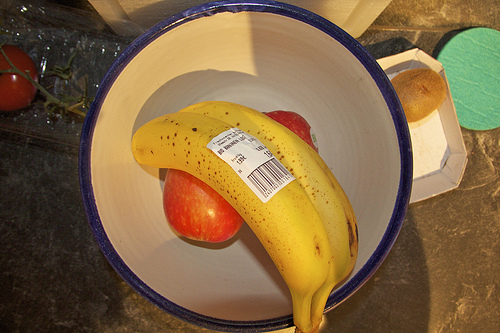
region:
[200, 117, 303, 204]
Sticker on the banana.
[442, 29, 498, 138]
Green disk on counter.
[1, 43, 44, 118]
Tomato on the vine.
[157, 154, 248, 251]
Apple in the bowl.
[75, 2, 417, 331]
Bowl on the counter.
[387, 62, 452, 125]
Kiwi on the container.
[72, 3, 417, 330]
Blue rim on bowl.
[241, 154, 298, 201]
Bar code on the sticker.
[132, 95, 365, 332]
yellow bananas in the bowl.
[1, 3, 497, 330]
Gray marble covering the surface.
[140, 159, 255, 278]
a piece of apple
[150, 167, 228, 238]
a piece of apple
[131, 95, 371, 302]
the bananas have freckles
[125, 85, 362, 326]
the two yellow bananas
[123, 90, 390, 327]
the two yellow bananas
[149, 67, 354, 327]
the two yellow bananas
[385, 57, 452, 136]
a piece of kiwi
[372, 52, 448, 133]
a piece of kiwi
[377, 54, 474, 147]
a piece of kiwi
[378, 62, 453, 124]
a piece of kiwi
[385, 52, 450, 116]
a piece of kiwi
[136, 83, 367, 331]
the bananas in the bowl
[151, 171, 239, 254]
thwe apple under the banana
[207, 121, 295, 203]
the sticker on the banana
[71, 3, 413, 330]
the fruit in the bowl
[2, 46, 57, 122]
the tomatoe on the broken glass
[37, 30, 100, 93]
the borken glass on the ground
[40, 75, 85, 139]
the vine of the tomato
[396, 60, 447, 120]
the brown kiwi in the white carton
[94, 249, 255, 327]
the blue trim of the bowl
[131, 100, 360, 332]
two yellow bananas in the bowl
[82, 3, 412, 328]
blue and white bowl holding fruit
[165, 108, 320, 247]
two red apples under bananas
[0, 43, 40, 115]
red tomato in plastic container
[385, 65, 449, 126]
one small bread roll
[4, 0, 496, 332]
marbled table top under food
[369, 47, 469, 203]
small white beveled edge dish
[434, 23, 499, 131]
round teal circular cloth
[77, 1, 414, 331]
blue rim on bowl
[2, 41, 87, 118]
stems with one tomato remaining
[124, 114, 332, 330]
yellow banana in the white bowl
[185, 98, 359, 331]
yellow banana in the white bowl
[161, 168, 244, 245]
A brighter apple in a bowl.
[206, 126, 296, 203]
Rectangle white sticker on a banana.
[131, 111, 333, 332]
Curved yellow banana with sticker on it.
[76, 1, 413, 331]
A blue rimmed white bowl.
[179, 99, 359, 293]
Yellow banana under another.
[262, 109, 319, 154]
Red apple with sticker on the side.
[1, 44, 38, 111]
A round red tomato.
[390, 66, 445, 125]
A brown kiwi fruit.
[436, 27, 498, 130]
A green round object.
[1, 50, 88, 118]
A green stem over a red tomato.